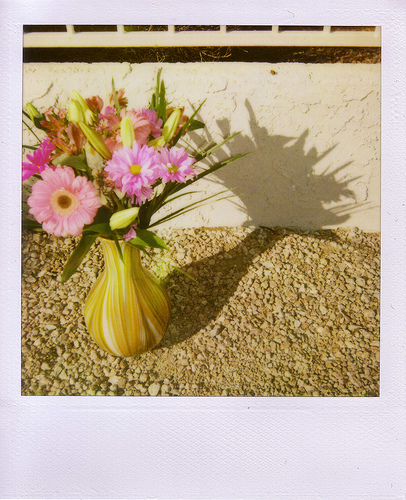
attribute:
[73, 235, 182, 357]
vase — yellow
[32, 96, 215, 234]
flowers — pink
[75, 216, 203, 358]
vase — yellow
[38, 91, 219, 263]
flower — pink, yellow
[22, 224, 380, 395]
gravel — golden brown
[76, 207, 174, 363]
vase — yellow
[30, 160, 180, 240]
flowers — pink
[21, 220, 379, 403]
ground — colored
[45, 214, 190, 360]
vase — yellow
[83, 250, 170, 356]
patches — white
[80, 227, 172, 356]
vase — yellow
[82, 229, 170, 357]
pot — golden brown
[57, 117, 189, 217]
flowers — pink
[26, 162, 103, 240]
flower — pink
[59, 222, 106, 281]
leaf — long, green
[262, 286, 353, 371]
gravel — beige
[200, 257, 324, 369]
gravel — beige